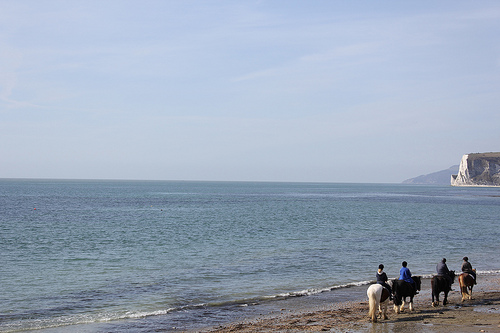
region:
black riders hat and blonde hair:
[359, 258, 388, 276]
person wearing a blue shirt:
[387, 248, 417, 290]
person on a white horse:
[332, 254, 399, 331]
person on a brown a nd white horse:
[376, 240, 421, 329]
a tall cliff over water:
[434, 144, 495, 199]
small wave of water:
[138, 268, 357, 330]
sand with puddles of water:
[298, 304, 449, 331]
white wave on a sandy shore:
[10, 278, 320, 328]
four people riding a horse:
[345, 247, 486, 327]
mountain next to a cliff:
[354, 150, 476, 205]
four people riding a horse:
[352, 250, 486, 325]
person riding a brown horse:
[451, 254, 486, 309]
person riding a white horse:
[356, 258, 401, 327]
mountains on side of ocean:
[408, 142, 499, 188]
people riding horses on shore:
[10, 176, 492, 331]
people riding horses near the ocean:
[128, 189, 499, 324]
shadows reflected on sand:
[393, 303, 497, 327]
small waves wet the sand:
[85, 280, 357, 328]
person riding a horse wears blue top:
[388, 250, 430, 310]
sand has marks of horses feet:
[256, 300, 358, 329]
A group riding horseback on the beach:
[357, 251, 495, 327]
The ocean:
[2, 174, 365, 300]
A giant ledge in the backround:
[450, 149, 498, 188]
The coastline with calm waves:
[202, 279, 355, 331]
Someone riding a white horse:
[356, 259, 408, 328]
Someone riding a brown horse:
[455, 256, 481, 307]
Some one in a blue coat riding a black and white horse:
[389, 253, 425, 320]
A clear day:
[0, 0, 440, 180]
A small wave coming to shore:
[6, 270, 338, 326]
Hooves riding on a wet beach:
[361, 296, 483, 329]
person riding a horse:
[355, 255, 398, 318]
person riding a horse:
[385, 255, 425, 321]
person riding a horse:
[420, 250, 460, 315]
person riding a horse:
[455, 250, 482, 301]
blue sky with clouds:
[0, 1, 495, 183]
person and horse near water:
[365, 255, 390, 320]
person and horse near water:
[386, 250, 421, 320]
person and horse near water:
[420, 251, 455, 306]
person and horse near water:
[452, 250, 482, 302]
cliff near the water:
[451, 147, 498, 199]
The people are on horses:
[329, 246, 496, 325]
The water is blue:
[102, 167, 229, 275]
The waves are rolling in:
[155, 280, 317, 332]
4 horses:
[334, 232, 498, 314]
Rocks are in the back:
[378, 126, 496, 205]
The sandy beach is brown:
[386, 283, 484, 330]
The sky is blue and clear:
[280, 60, 445, 182]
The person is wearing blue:
[389, 251, 420, 296]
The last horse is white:
[334, 263, 438, 329]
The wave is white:
[50, 299, 201, 331]